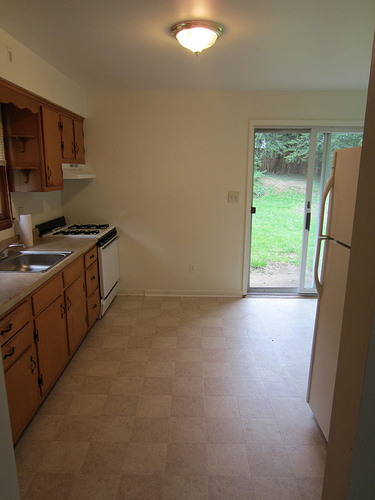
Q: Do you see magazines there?
A: No, there are no magazines.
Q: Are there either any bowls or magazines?
A: No, there are no magazines or bowls.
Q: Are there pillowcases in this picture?
A: No, there are no pillowcases.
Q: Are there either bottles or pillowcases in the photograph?
A: No, there are no pillowcases or bottles.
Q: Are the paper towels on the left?
A: Yes, the paper towels are on the left of the image.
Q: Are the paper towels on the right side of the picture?
A: No, the paper towels are on the left of the image.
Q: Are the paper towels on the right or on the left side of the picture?
A: The paper towels are on the left of the image.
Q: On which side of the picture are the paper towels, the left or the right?
A: The paper towels are on the left of the image.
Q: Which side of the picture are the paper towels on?
A: The paper towels are on the left of the image.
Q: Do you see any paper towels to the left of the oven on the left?
A: Yes, there are paper towels to the left of the oven.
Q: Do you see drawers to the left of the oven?
A: No, there are paper towels to the left of the oven.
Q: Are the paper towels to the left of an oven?
A: Yes, the paper towels are to the left of an oven.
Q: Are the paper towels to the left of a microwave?
A: No, the paper towels are to the left of an oven.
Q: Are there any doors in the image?
A: Yes, there is a door.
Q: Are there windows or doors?
A: Yes, there is a door.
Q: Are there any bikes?
A: No, there are no bikes.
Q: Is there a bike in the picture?
A: No, there are no bikes.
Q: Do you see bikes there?
A: No, there are no bikes.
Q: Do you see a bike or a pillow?
A: No, there are no bikes or pillows.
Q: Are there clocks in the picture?
A: No, there are no clocks.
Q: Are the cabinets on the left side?
A: Yes, the cabinets are on the left of the image.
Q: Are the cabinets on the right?
A: No, the cabinets are on the left of the image.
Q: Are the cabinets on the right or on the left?
A: The cabinets are on the left of the image.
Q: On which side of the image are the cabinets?
A: The cabinets are on the left of the image.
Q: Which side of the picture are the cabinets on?
A: The cabinets are on the left of the image.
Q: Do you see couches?
A: No, there are no couches.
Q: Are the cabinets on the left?
A: Yes, the cabinets are on the left of the image.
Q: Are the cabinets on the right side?
A: No, the cabinets are on the left of the image.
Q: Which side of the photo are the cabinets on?
A: The cabinets are on the left of the image.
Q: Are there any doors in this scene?
A: Yes, there is a door.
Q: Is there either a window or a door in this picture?
A: Yes, there is a door.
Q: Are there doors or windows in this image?
A: Yes, there is a door.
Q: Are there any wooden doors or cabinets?
A: Yes, there is a wood door.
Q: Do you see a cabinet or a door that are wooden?
A: Yes, the door is wooden.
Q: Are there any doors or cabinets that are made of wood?
A: Yes, the door is made of wood.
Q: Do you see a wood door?
A: Yes, there is a wood door.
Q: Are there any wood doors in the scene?
A: Yes, there is a wood door.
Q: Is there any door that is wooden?
A: Yes, there is a door that is wooden.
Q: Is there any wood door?
A: Yes, there is a door that is made of wood.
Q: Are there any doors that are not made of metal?
A: Yes, there is a door that is made of wood.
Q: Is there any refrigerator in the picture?
A: Yes, there is a refrigerator.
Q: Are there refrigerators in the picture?
A: Yes, there is a refrigerator.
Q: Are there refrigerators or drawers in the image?
A: Yes, there is a refrigerator.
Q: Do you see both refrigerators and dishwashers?
A: No, there is a refrigerator but no dishwashers.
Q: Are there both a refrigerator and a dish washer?
A: No, there is a refrigerator but no dishwashers.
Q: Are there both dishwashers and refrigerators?
A: No, there is a refrigerator but no dishwashers.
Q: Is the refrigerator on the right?
A: Yes, the refrigerator is on the right of the image.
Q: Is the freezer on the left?
A: No, the freezer is on the right of the image.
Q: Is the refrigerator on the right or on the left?
A: The refrigerator is on the right of the image.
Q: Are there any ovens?
A: Yes, there is an oven.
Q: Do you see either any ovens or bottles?
A: Yes, there is an oven.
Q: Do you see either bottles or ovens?
A: Yes, there is an oven.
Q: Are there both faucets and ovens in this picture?
A: Yes, there are both an oven and a faucet.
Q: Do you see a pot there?
A: No, there are no pots.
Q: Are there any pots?
A: No, there are no pots.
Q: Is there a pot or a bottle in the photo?
A: No, there are no pots or bottles.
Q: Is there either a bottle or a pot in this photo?
A: No, there are no pots or bottles.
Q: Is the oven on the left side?
A: Yes, the oven is on the left of the image.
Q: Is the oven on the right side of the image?
A: No, the oven is on the left of the image.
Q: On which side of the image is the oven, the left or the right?
A: The oven is on the left of the image.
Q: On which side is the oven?
A: The oven is on the left of the image.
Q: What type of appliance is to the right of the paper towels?
A: The appliance is an oven.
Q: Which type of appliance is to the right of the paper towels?
A: The appliance is an oven.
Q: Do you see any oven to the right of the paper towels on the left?
A: Yes, there is an oven to the right of the paper towels.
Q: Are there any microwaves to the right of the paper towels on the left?
A: No, there is an oven to the right of the paper towels.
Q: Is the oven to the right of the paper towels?
A: Yes, the oven is to the right of the paper towels.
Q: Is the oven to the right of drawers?
A: No, the oven is to the right of the paper towels.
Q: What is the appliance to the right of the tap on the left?
A: The appliance is an oven.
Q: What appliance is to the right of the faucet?
A: The appliance is an oven.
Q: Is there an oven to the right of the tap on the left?
A: Yes, there is an oven to the right of the tap.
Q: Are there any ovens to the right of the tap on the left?
A: Yes, there is an oven to the right of the tap.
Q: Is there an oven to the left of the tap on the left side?
A: No, the oven is to the right of the tap.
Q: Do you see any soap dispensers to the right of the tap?
A: No, there is an oven to the right of the tap.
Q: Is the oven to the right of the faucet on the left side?
A: Yes, the oven is to the right of the tap.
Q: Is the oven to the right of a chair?
A: No, the oven is to the right of the tap.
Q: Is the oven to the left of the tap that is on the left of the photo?
A: No, the oven is to the right of the faucet.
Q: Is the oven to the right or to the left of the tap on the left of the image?
A: The oven is to the right of the faucet.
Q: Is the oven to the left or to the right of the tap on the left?
A: The oven is to the right of the faucet.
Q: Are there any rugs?
A: No, there are no rugs.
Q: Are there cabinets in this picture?
A: Yes, there is a cabinet.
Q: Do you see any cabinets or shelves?
A: Yes, there is a cabinet.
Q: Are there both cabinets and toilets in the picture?
A: No, there is a cabinet but no toilets.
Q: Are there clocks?
A: No, there are no clocks.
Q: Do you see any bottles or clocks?
A: No, there are no clocks or bottles.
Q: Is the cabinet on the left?
A: Yes, the cabinet is on the left of the image.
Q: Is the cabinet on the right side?
A: No, the cabinet is on the left of the image.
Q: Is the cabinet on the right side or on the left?
A: The cabinet is on the left of the image.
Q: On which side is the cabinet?
A: The cabinet is on the left of the image.